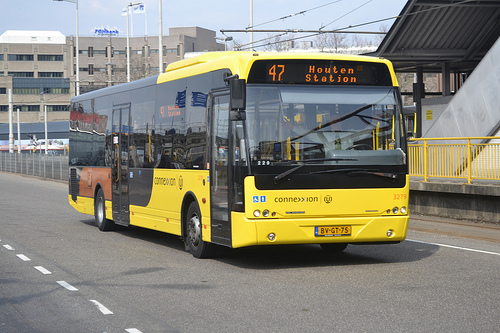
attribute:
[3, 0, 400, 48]
daytime sky — blue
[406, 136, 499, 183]
rails — yellow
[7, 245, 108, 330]
lines — white, broken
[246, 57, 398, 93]
words — on display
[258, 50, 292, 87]
number 47 — bus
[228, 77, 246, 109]
mirror — side view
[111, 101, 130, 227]
back door — in back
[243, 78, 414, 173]
windshield — black, wipers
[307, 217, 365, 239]
license plate — yellow, in front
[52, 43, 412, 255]
bus — yellow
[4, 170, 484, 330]
street — paved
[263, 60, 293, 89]
numbers — on display